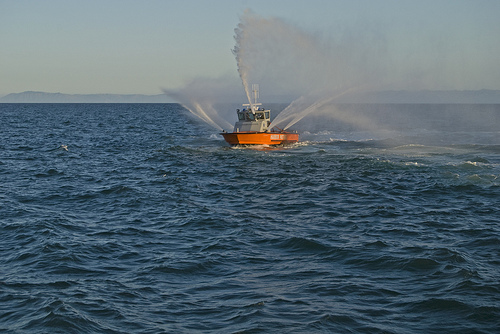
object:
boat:
[219, 84, 299, 147]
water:
[231, 19, 272, 105]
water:
[269, 91, 354, 130]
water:
[163, 85, 234, 132]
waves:
[277, 228, 447, 275]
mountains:
[339, 88, 500, 103]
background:
[1, 2, 498, 104]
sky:
[0, 5, 498, 95]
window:
[238, 113, 244, 120]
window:
[247, 113, 255, 121]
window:
[257, 113, 264, 120]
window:
[265, 112, 269, 119]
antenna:
[251, 80, 260, 103]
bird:
[61, 145, 68, 152]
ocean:
[0, 104, 500, 334]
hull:
[220, 130, 268, 147]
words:
[271, 135, 285, 139]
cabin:
[234, 114, 271, 132]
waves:
[91, 172, 151, 200]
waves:
[368, 142, 471, 172]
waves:
[23, 273, 109, 327]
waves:
[35, 106, 179, 145]